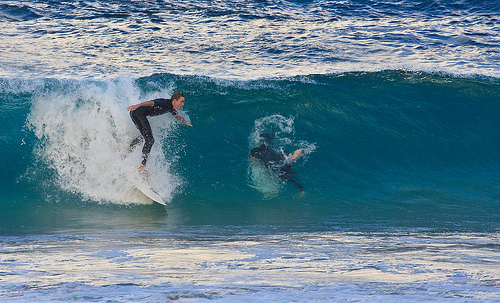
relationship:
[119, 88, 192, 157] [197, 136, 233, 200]
surfer in water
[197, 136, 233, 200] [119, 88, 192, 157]
water splashing next to surfer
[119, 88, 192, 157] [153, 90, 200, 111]
surfer facing right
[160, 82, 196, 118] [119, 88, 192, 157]
head of surfer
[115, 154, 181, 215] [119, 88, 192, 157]
board below surfer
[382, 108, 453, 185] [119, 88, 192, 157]
blue ocean next to surfer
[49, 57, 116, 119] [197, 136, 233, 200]
ripples in water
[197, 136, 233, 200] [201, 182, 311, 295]
water in foreground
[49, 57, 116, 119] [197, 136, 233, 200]
wave forming in water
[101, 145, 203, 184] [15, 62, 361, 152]
surfing on wave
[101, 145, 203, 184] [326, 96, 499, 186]
surfing in blue ocean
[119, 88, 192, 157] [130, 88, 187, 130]
man wearing wet suite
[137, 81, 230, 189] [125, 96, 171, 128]
man with arms out to side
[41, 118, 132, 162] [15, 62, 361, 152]
white water on wave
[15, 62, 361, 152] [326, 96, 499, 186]
wave in blue ocean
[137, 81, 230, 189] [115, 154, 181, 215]
man on board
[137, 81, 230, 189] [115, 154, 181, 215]
man standing on board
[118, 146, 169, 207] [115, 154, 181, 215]
board short board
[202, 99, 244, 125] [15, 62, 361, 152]
section of wave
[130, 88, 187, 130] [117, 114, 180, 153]
black short sleeved rashguard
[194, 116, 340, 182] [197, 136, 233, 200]
person under water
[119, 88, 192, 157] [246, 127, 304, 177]
surfer looking at swimmer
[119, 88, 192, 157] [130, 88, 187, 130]
surfer arms are outstretched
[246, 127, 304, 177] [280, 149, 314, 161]
swimmer sticking up foot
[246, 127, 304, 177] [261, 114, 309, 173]
swimmer foot down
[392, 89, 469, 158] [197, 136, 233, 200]
greenish color to water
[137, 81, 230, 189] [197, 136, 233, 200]
man in water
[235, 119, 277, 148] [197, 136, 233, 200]
thing in water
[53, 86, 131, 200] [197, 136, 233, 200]
white water in water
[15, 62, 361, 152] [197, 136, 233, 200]
wave forming on water